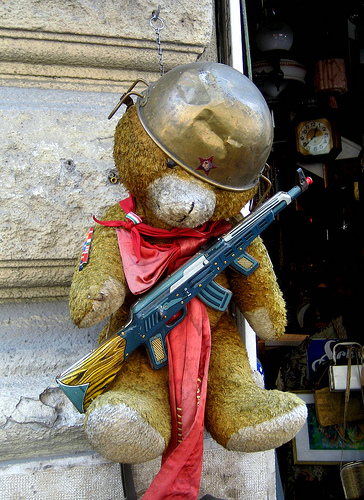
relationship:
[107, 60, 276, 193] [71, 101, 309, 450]
bowl on bear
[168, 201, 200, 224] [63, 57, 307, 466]
nose on bear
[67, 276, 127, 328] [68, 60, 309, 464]
paw on bear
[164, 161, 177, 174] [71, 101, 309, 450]
eye on bear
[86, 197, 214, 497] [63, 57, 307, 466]
red scarf on bear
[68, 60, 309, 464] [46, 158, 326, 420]
bear with gun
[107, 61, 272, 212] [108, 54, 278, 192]
pan used as helmet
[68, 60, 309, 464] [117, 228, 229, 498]
bear with scarf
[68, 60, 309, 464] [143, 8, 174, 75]
bear hanging from chain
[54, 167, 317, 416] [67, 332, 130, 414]
gun with butt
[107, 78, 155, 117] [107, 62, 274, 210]
handle of pot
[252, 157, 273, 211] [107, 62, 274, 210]
handle of pot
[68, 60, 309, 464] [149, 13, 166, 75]
bear hangs on chain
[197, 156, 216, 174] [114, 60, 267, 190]
insignia on helmet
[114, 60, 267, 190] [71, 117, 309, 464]
helmet of teddy bear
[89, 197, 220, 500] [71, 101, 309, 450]
red scarf on bear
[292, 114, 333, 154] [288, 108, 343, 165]
hands on clock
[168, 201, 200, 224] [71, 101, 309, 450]
nose on bear